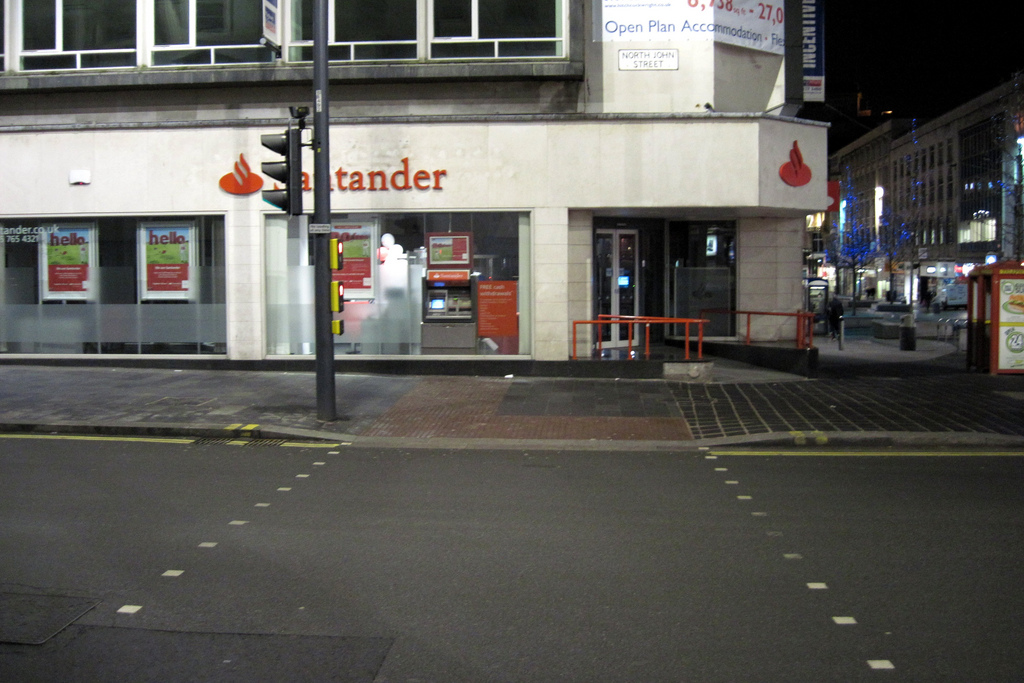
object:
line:
[0, 433, 337, 449]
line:
[710, 450, 1022, 457]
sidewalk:
[0, 360, 1024, 444]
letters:
[273, 157, 446, 191]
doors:
[592, 229, 639, 351]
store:
[0, 0, 830, 375]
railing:
[699, 308, 816, 349]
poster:
[140, 221, 192, 300]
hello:
[150, 230, 186, 245]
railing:
[570, 314, 710, 361]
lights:
[826, 166, 914, 266]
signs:
[38, 224, 99, 305]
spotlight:
[262, 128, 305, 217]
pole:
[315, 0, 335, 422]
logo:
[219, 152, 447, 196]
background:
[0, 115, 835, 213]